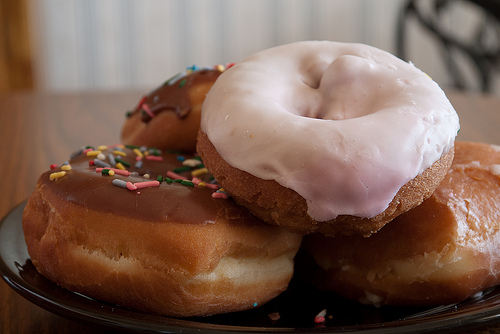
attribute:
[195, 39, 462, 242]
donut — frosted, delicious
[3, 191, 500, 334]
plate — black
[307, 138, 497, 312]
donut — glazed, honey dipped, delicious, normal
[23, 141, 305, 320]
donut — delicious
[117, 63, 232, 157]
donut — delicious, sprinkled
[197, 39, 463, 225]
frosting — white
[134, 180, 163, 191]
sprinkle — small, pink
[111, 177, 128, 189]
sprinkle — small, rainbow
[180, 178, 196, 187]
sprinkle — small, rainbow colored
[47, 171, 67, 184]
sprinkle — small, rainbow, yellow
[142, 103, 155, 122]
sprinkle — pink, small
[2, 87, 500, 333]
table — brown, wooden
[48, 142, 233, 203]
sprinkles — multicolored, rainbow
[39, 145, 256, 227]
frosting — chocolate, brown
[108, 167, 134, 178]
sprinkle — small, rainbow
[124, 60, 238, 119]
sprinkles — multicolored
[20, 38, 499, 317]
donuts — assorted